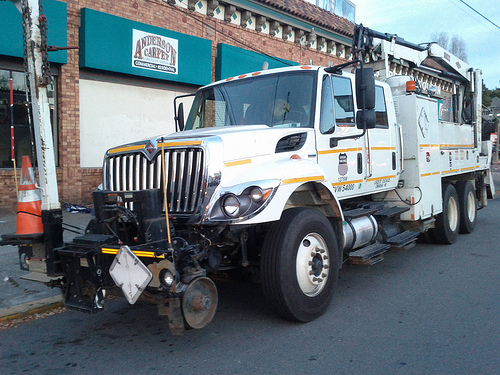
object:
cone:
[14, 156, 43, 234]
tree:
[431, 31, 469, 64]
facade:
[2, 1, 369, 208]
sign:
[131, 27, 179, 77]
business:
[12, 2, 400, 215]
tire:
[251, 207, 340, 324]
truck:
[45, 23, 496, 338]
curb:
[9, 152, 479, 329]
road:
[0, 157, 496, 374]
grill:
[102, 146, 204, 216]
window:
[331, 74, 356, 127]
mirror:
[354, 67, 376, 109]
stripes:
[316, 147, 363, 155]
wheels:
[181, 276, 219, 329]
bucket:
[385, 75, 412, 96]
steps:
[386, 229, 419, 246]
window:
[0, 67, 59, 169]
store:
[3, 3, 467, 216]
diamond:
[109, 244, 153, 305]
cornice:
[182, 1, 355, 37]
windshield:
[183, 70, 318, 131]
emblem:
[337, 153, 348, 177]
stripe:
[106, 139, 201, 155]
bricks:
[0, 0, 361, 214]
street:
[0, 172, 497, 372]